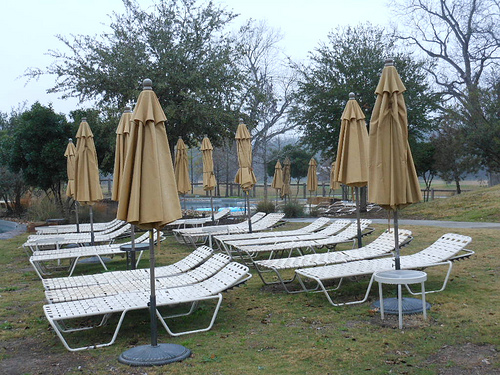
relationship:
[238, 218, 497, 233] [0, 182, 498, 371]
path through grass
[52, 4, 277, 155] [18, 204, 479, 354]
tree behind chairs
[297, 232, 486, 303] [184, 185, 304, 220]
chairs near pool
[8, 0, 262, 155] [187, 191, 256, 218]
tree behind pool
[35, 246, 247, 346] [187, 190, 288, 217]
beach chairs near pool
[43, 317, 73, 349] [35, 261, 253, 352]
leg of beach chairs